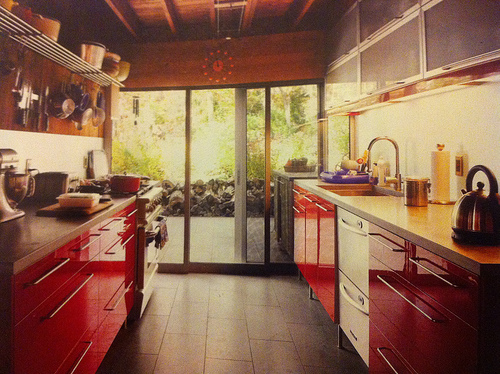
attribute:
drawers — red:
[1, 215, 166, 371]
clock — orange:
[190, 39, 242, 100]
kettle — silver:
[441, 159, 499, 244]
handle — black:
[454, 159, 495, 195]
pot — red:
[108, 171, 142, 196]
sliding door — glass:
[174, 86, 279, 278]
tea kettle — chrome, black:
[445, 159, 497, 239]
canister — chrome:
[401, 166, 435, 216]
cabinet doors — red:
[288, 175, 342, 313]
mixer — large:
[0, 135, 38, 231]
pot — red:
[107, 168, 150, 204]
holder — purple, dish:
[315, 160, 371, 184]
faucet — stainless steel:
[365, 134, 405, 194]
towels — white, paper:
[429, 148, 454, 205]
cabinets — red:
[354, 218, 494, 373]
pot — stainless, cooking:
[73, 35, 115, 73]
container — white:
[54, 188, 100, 212]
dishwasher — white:
[328, 207, 377, 360]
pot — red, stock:
[107, 169, 147, 197]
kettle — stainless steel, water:
[444, 161, 498, 250]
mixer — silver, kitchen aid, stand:
[4, 147, 36, 227]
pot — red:
[102, 169, 145, 197]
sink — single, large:
[324, 185, 399, 201]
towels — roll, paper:
[424, 147, 449, 207]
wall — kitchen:
[343, 70, 498, 215]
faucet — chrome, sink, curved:
[364, 134, 410, 199]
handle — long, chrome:
[375, 272, 440, 323]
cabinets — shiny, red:
[6, 197, 146, 373]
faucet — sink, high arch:
[361, 134, 402, 194]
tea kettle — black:
[449, 168, 484, 234]